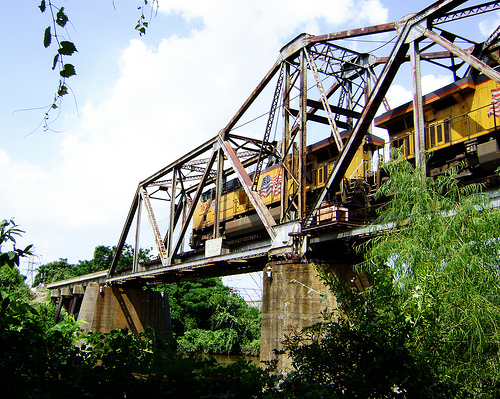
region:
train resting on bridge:
[85, 3, 497, 392]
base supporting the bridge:
[247, 251, 380, 397]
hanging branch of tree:
[30, 3, 94, 143]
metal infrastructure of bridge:
[103, 180, 183, 277]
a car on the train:
[181, 123, 371, 235]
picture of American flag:
[257, 170, 294, 202]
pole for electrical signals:
[24, 240, 44, 288]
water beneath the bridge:
[212, 349, 260, 364]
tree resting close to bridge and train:
[362, 156, 499, 393]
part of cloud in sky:
[104, 42, 244, 99]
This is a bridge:
[8, 5, 493, 366]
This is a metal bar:
[129, 172, 146, 291]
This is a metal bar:
[203, 133, 230, 275]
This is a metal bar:
[295, 38, 318, 238]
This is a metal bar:
[273, 41, 292, 243]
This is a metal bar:
[401, 24, 437, 236]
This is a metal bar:
[303, 38, 350, 155]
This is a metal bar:
[171, 133, 218, 248]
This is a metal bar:
[142, 165, 164, 271]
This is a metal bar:
[106, 186, 137, 299]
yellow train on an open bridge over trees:
[161, 55, 498, 250]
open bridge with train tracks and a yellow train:
[7, 0, 496, 290]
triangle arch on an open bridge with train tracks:
[94, 176, 171, 285]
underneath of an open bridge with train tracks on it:
[93, 254, 313, 395]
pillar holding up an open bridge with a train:
[251, 249, 358, 397]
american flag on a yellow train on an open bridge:
[250, 167, 292, 209]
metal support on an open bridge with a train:
[273, 32, 318, 243]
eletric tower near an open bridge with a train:
[15, 240, 44, 295]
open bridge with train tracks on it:
[40, 261, 113, 351]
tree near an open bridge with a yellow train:
[326, 156, 498, 397]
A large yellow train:
[189, 68, 499, 245]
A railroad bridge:
[105, 192, 499, 287]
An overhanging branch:
[20, 3, 82, 141]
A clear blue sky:
[0, 2, 498, 291]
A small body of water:
[176, 346, 257, 364]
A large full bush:
[351, 149, 498, 396]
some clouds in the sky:
[0, 1, 460, 306]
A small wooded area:
[31, 245, 258, 354]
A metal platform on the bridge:
[298, 200, 358, 232]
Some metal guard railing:
[302, 203, 369, 226]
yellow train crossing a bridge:
[188, 65, 498, 255]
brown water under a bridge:
[101, 340, 273, 390]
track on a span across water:
[25, 190, 499, 284]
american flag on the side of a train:
[254, 170, 288, 201]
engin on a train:
[175, 117, 380, 252]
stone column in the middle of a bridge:
[251, 249, 394, 389]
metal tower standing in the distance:
[18, 241, 43, 290]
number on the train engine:
[195, 201, 215, 215]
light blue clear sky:
[1, 0, 498, 252]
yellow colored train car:
[371, 60, 499, 205]